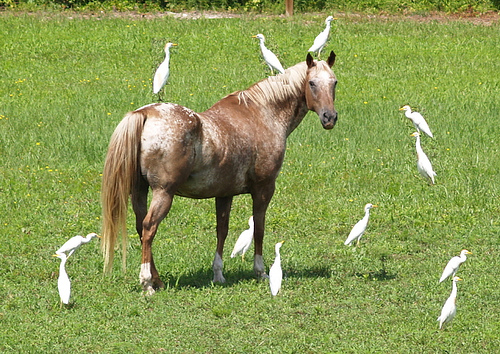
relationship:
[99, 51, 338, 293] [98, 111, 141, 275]
horse has tail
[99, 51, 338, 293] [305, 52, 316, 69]
horse has ear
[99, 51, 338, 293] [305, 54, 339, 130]
horse has head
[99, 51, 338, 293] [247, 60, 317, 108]
horse has mane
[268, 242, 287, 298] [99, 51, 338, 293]
bird by horse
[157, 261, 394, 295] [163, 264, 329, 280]
grass has shadow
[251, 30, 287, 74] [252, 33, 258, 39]
bird has beak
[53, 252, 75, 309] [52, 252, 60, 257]
bird has beak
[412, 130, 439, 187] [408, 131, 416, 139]
bird has beak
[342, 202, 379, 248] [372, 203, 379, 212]
bird has beak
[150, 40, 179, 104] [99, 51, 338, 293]
bird on top of horse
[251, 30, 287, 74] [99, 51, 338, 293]
bird on top of horse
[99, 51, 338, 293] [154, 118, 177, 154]
horse has patches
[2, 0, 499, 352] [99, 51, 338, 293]
field has horse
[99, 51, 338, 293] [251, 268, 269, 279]
horse has hoof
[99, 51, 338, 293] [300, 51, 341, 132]
horse has face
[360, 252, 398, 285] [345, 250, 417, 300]
shadow on ground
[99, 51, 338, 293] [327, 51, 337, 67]
horse has ear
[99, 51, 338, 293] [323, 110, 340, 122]
horse has nose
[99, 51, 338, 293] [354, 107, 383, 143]
horse on green grass